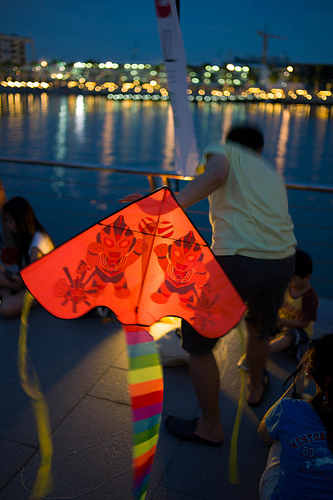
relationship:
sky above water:
[4, 4, 331, 63] [11, 98, 332, 255]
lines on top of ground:
[11, 349, 177, 487] [14, 302, 326, 499]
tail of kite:
[123, 321, 163, 495] [24, 196, 247, 330]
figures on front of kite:
[92, 228, 204, 301] [24, 196, 247, 330]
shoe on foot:
[168, 418, 198, 440] [167, 415, 223, 446]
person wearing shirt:
[257, 341, 332, 498] [265, 401, 330, 499]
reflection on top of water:
[20, 100, 331, 140] [11, 98, 332, 255]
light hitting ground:
[115, 315, 190, 351] [14, 302, 326, 499]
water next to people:
[11, 98, 332, 255] [13, 123, 331, 494]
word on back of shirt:
[289, 422, 327, 450] [265, 401, 330, 499]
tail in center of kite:
[123, 321, 163, 495] [24, 196, 247, 330]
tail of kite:
[19, 290, 56, 498] [24, 196, 247, 330]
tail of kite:
[226, 324, 246, 490] [24, 196, 247, 330]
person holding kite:
[185, 128, 288, 425] [24, 196, 247, 330]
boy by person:
[277, 253, 319, 354] [185, 128, 288, 425]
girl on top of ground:
[2, 196, 55, 318] [14, 302, 326, 499]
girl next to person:
[2, 196, 55, 318] [185, 128, 288, 425]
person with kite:
[185, 128, 288, 425] [24, 196, 247, 330]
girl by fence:
[2, 196, 55, 318] [2, 165, 331, 318]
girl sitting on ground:
[2, 196, 55, 318] [14, 302, 326, 499]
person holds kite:
[185, 128, 288, 425] [24, 196, 247, 330]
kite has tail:
[24, 196, 247, 330] [123, 321, 163, 495]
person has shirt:
[185, 128, 288, 425] [202, 143, 299, 254]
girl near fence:
[2, 196, 55, 318] [2, 165, 331, 318]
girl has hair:
[2, 196, 55, 318] [13, 201, 41, 260]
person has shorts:
[185, 128, 288, 425] [193, 249, 299, 331]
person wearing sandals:
[185, 128, 288, 425] [155, 369, 273, 448]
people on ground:
[13, 123, 331, 494] [14, 302, 326, 499]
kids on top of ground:
[270, 258, 331, 494] [14, 302, 326, 499]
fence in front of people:
[2, 165, 331, 318] [13, 123, 331, 494]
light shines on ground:
[115, 315, 190, 351] [14, 302, 326, 499]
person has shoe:
[185, 128, 288, 425] [168, 418, 198, 440]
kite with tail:
[24, 196, 247, 330] [123, 321, 163, 495]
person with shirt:
[185, 128, 288, 425] [202, 143, 299, 254]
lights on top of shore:
[14, 68, 331, 104] [6, 32, 329, 106]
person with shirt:
[257, 341, 332, 498] [265, 401, 330, 499]